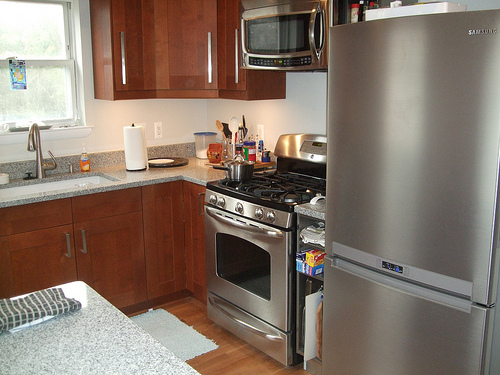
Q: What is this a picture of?
A: A kitchen.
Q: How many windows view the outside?
A: One.